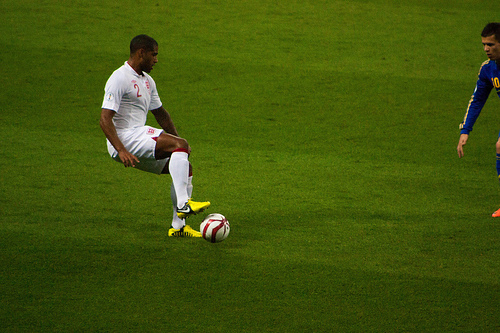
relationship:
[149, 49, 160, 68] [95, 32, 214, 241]
face of man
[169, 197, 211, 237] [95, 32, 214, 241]
shoes of man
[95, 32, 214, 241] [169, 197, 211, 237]
man wearing shoes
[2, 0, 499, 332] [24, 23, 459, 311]
grass on field